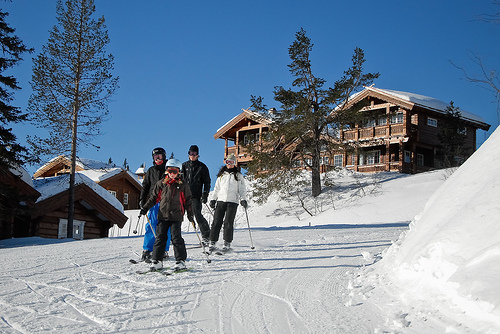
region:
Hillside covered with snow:
[383, 113, 499, 313]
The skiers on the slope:
[127, 139, 257, 283]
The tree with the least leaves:
[27, 0, 119, 243]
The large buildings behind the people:
[209, 83, 493, 173]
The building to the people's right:
[1, 155, 159, 253]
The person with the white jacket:
[205, 153, 247, 255]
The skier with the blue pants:
[136, 145, 173, 262]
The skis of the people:
[125, 244, 245, 277]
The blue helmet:
[163, 155, 183, 173]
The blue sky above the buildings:
[0, 0, 499, 177]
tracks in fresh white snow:
[102, 273, 299, 333]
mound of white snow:
[361, 180, 483, 280]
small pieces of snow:
[335, 275, 379, 326]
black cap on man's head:
[140, 143, 170, 158]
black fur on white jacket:
[218, 165, 255, 180]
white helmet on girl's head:
[162, 151, 190, 169]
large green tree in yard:
[23, 11, 128, 174]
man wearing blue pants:
[125, 198, 197, 259]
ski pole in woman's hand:
[240, 201, 269, 253]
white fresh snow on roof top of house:
[30, 163, 132, 222]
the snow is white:
[276, 240, 336, 306]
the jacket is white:
[210, 168, 254, 221]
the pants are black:
[208, 200, 250, 245]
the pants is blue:
[135, 202, 165, 248]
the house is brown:
[332, 95, 451, 185]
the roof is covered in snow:
[345, 71, 480, 132]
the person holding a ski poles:
[195, 176, 264, 253]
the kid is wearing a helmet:
[155, 155, 179, 178]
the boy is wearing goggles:
[162, 166, 187, 181]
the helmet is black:
[144, 140, 171, 160]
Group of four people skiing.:
[127, 140, 258, 277]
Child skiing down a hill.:
[132, 156, 196, 276]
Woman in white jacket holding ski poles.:
[209, 150, 258, 257]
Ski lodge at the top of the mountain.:
[214, 82, 491, 176]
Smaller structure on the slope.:
[27, 174, 130, 238]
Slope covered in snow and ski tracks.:
[2, 222, 421, 332]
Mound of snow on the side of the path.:
[357, 122, 498, 332]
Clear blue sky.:
[0, 1, 498, 176]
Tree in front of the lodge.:
[246, 28, 381, 212]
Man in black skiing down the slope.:
[178, 141, 213, 250]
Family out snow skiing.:
[122, 139, 259, 277]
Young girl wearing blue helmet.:
[161, 157, 187, 171]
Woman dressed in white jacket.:
[208, 170, 252, 207]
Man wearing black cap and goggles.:
[182, 143, 206, 163]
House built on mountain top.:
[218, 83, 493, 190]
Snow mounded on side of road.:
[381, 138, 498, 333]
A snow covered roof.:
[33, 166, 130, 214]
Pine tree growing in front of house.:
[240, 18, 382, 208]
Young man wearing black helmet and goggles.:
[149, 145, 167, 166]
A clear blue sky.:
[136, 26, 223, 117]